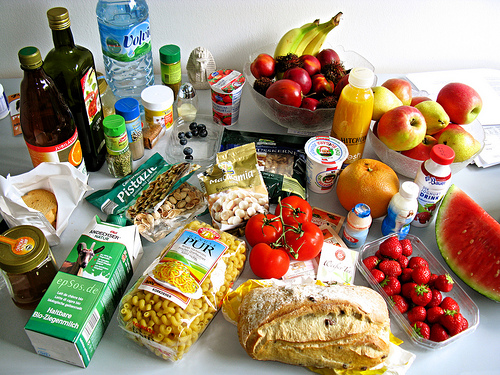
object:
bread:
[238, 280, 391, 371]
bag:
[85, 153, 208, 244]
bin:
[381, 181, 420, 241]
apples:
[377, 105, 427, 151]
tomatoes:
[244, 213, 283, 247]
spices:
[105, 150, 132, 178]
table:
[196, 341, 238, 366]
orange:
[336, 158, 400, 219]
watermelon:
[436, 184, 500, 305]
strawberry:
[428, 273, 437, 289]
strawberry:
[386, 295, 407, 315]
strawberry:
[440, 309, 464, 337]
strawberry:
[460, 317, 468, 333]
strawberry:
[397, 254, 409, 269]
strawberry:
[430, 323, 449, 342]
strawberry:
[379, 236, 402, 261]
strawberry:
[409, 256, 429, 270]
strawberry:
[402, 268, 413, 280]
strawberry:
[369, 269, 386, 285]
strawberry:
[374, 249, 384, 260]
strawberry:
[408, 306, 427, 323]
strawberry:
[440, 296, 459, 314]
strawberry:
[428, 288, 442, 307]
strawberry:
[363, 255, 379, 271]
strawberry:
[434, 273, 454, 292]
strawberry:
[398, 238, 413, 257]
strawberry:
[379, 275, 401, 296]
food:
[249, 242, 289, 279]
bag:
[116, 220, 250, 367]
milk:
[23, 215, 144, 368]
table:
[98, 343, 134, 366]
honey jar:
[0, 225, 59, 310]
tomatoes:
[282, 221, 324, 261]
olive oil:
[43, 46, 109, 172]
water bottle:
[95, 0, 157, 99]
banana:
[273, 18, 320, 80]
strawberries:
[410, 283, 433, 307]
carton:
[356, 232, 480, 352]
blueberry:
[183, 147, 193, 155]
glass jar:
[103, 114, 136, 179]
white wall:
[167, 0, 263, 37]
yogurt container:
[303, 135, 349, 194]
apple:
[436, 82, 482, 125]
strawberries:
[411, 266, 430, 285]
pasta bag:
[219, 127, 309, 205]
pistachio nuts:
[185, 201, 195, 210]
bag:
[196, 142, 270, 238]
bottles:
[42, 7, 108, 173]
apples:
[402, 135, 438, 161]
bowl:
[368, 118, 487, 181]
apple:
[438, 128, 476, 163]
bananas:
[295, 16, 336, 58]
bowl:
[242, 42, 379, 133]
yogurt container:
[207, 69, 246, 128]